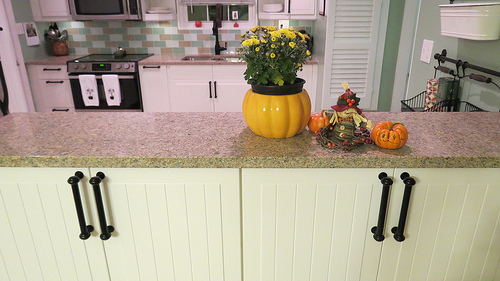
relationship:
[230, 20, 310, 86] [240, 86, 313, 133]
plant inside vase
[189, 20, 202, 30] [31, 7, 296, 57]
fruit on wall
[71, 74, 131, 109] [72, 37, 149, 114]
hand towels are on stove